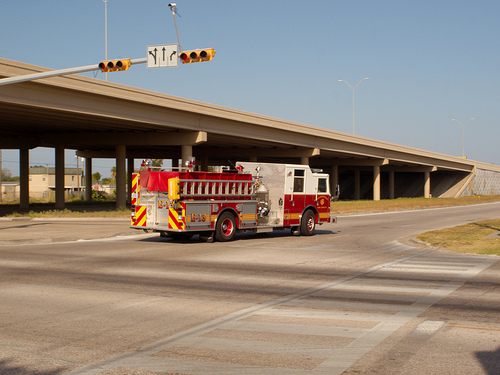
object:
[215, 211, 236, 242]
tire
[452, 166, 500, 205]
wall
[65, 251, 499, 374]
crosswalk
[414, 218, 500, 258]
grass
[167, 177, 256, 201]
ladder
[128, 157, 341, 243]
fire truck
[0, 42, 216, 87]
pole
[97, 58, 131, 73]
traffic lights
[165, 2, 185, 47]
camera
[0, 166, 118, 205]
building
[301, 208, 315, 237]
tire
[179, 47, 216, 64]
traffic licght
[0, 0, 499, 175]
sky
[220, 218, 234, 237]
rim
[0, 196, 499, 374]
road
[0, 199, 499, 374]
ground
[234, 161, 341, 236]
cab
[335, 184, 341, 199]
mirror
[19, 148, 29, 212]
column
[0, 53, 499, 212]
bridge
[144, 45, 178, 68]
sign